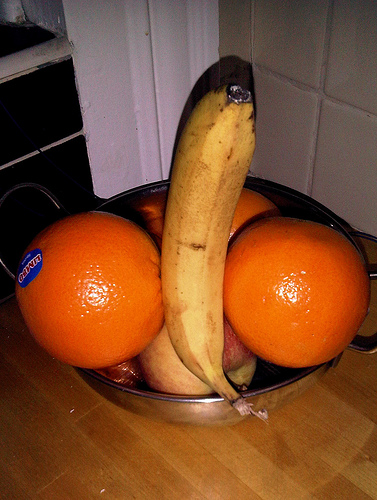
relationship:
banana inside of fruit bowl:
[160, 82, 255, 424] [56, 175, 375, 426]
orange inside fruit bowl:
[15, 209, 163, 371] [56, 175, 375, 426]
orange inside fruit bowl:
[223, 217, 370, 369] [56, 175, 375, 426]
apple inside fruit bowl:
[141, 301, 256, 400] [56, 175, 375, 426]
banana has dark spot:
[160, 82, 255, 424] [181, 238, 210, 254]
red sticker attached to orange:
[15, 249, 45, 287] [15, 209, 163, 371]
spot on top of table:
[67, 406, 77, 416] [0, 225, 373, 499]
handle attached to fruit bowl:
[349, 269, 375, 354] [56, 175, 375, 426]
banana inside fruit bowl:
[160, 82, 255, 424] [56, 175, 375, 426]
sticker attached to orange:
[15, 249, 45, 287] [15, 209, 163, 371]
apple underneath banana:
[141, 301, 256, 400] [160, 82, 255, 424]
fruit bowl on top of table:
[56, 175, 375, 426] [0, 225, 373, 499]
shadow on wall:
[178, 56, 257, 165] [220, 2, 375, 239]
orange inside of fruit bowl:
[15, 209, 163, 371] [56, 175, 375, 426]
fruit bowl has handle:
[56, 175, 375, 426] [349, 269, 375, 354]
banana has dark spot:
[160, 82, 255, 424] [227, 84, 251, 107]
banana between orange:
[160, 82, 255, 424] [15, 209, 163, 371]